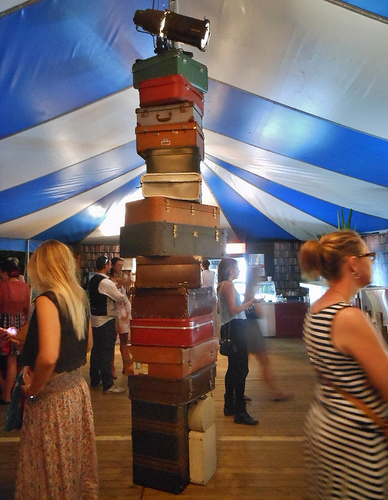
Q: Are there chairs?
A: No, there are no chairs.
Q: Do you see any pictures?
A: No, there are no pictures.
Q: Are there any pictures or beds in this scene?
A: No, there are no pictures or beds.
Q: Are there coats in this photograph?
A: Yes, there is a coat.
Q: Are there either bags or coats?
A: Yes, there is a coat.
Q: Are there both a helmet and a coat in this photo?
A: No, there is a coat but no helmets.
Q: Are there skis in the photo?
A: No, there are no skis.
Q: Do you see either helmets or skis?
A: No, there are no skis or helmets.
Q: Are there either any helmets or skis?
A: No, there are no skis or helmets.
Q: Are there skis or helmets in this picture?
A: No, there are no skis or helmets.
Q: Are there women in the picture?
A: Yes, there is a woman.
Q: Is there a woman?
A: Yes, there is a woman.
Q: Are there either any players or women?
A: Yes, there is a woman.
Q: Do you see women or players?
A: Yes, there is a woman.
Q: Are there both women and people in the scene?
A: Yes, there are both a woman and people.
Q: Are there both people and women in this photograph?
A: Yes, there are both a woman and people.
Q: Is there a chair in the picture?
A: No, there are no chairs.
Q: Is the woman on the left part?
A: Yes, the woman is on the left of the image.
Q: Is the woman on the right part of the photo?
A: No, the woman is on the left of the image.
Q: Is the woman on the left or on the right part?
A: The woman is on the left of the image.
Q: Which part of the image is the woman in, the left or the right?
A: The woman is on the left of the image.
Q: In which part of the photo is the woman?
A: The woman is on the left of the image.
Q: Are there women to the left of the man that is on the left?
A: Yes, there is a woman to the left of the man.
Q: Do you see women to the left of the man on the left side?
A: Yes, there is a woman to the left of the man.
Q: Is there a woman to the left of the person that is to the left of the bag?
A: Yes, there is a woman to the left of the man.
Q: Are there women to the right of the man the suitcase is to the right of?
A: No, the woman is to the left of the man.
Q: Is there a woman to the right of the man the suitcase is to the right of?
A: No, the woman is to the left of the man.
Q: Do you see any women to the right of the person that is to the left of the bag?
A: No, the woman is to the left of the man.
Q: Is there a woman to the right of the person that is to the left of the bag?
A: No, the woman is to the left of the man.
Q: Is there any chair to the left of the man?
A: No, there is a woman to the left of the man.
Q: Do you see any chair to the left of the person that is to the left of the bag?
A: No, there is a woman to the left of the man.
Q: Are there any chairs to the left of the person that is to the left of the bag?
A: No, there is a woman to the left of the man.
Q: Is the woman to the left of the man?
A: Yes, the woman is to the left of the man.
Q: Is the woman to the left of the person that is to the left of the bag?
A: Yes, the woman is to the left of the man.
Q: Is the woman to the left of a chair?
A: No, the woman is to the left of the man.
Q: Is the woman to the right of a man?
A: No, the woman is to the left of a man.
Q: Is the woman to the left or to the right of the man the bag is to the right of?
A: The woman is to the left of the man.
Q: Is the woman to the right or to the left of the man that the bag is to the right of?
A: The woman is to the left of the man.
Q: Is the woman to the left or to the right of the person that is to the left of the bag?
A: The woman is to the left of the man.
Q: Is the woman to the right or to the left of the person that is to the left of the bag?
A: The woman is to the left of the man.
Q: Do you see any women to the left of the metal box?
A: Yes, there is a woman to the left of the box.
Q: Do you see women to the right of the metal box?
A: No, the woman is to the left of the box.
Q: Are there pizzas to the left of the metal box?
A: No, there is a woman to the left of the box.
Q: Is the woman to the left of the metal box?
A: Yes, the woman is to the left of the box.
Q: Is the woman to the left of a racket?
A: No, the woman is to the left of the box.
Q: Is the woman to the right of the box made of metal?
A: No, the woman is to the left of the box.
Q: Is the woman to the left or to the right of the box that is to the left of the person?
A: The woman is to the left of the box.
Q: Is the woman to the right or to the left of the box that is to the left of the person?
A: The woman is to the left of the box.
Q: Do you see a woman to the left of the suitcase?
A: Yes, there is a woman to the left of the suitcase.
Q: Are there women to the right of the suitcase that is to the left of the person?
A: No, the woman is to the left of the suitcase.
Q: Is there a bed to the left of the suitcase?
A: No, there is a woman to the left of the suitcase.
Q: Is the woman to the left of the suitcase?
A: Yes, the woman is to the left of the suitcase.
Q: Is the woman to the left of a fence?
A: No, the woman is to the left of the suitcase.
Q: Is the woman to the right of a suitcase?
A: No, the woman is to the left of a suitcase.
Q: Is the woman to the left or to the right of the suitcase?
A: The woman is to the left of the suitcase.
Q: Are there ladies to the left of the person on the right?
A: Yes, there is a lady to the left of the person.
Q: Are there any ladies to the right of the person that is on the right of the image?
A: No, the lady is to the left of the person.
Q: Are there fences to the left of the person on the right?
A: No, there is a lady to the left of the person.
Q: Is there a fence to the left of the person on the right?
A: No, there is a lady to the left of the person.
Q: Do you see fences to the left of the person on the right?
A: No, there is a lady to the left of the person.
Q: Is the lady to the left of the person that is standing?
A: Yes, the lady is to the left of the person.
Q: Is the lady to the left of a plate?
A: No, the lady is to the left of the person.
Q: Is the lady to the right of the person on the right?
A: No, the lady is to the left of the person.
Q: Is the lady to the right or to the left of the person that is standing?
A: The lady is to the left of the person.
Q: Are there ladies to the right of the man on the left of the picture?
A: Yes, there is a lady to the right of the man.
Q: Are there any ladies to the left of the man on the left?
A: No, the lady is to the right of the man.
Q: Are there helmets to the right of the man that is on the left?
A: No, there is a lady to the right of the man.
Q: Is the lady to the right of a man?
A: Yes, the lady is to the right of a man.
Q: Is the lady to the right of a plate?
A: No, the lady is to the right of a man.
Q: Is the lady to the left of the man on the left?
A: No, the lady is to the right of the man.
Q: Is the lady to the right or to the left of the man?
A: The lady is to the right of the man.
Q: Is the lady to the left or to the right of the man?
A: The lady is to the right of the man.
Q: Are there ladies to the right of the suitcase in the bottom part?
A: Yes, there is a lady to the right of the suitcase.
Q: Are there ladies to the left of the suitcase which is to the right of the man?
A: No, the lady is to the right of the suitcase.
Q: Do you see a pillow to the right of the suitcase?
A: No, there is a lady to the right of the suitcase.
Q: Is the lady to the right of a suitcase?
A: Yes, the lady is to the right of a suitcase.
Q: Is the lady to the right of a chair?
A: No, the lady is to the right of a suitcase.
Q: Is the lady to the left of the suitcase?
A: No, the lady is to the right of the suitcase.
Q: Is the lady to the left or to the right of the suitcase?
A: The lady is to the right of the suitcase.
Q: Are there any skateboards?
A: No, there are no skateboards.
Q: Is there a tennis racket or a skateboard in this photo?
A: No, there are no skateboards or rackets.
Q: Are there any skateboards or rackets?
A: No, there are no skateboards or rackets.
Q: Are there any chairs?
A: No, there are no chairs.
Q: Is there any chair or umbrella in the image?
A: No, there are no chairs or umbrellas.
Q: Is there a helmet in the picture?
A: No, there are no helmets.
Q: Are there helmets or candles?
A: No, there are no helmets or candles.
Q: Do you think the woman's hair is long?
A: Yes, the hair is long.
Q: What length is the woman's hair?
A: The hair is long.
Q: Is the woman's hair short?
A: No, the hair is long.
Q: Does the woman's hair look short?
A: No, the hair is long.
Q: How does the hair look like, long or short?
A: The hair is long.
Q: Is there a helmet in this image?
A: No, there are no helmets.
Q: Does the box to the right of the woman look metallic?
A: Yes, the box is metallic.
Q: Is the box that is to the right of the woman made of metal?
A: Yes, the box is made of metal.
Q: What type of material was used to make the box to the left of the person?
A: The box is made of metal.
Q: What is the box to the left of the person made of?
A: The box is made of metal.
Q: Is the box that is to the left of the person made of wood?
A: No, the box is made of metal.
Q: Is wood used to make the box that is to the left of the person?
A: No, the box is made of metal.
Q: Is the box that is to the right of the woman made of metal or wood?
A: The box is made of metal.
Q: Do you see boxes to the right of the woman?
A: Yes, there is a box to the right of the woman.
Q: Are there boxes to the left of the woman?
A: No, the box is to the right of the woman.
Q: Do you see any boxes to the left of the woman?
A: No, the box is to the right of the woman.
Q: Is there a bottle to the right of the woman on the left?
A: No, there is a box to the right of the woman.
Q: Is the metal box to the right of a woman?
A: Yes, the box is to the right of a woman.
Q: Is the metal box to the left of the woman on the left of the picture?
A: No, the box is to the right of the woman.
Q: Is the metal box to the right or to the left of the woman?
A: The box is to the right of the woman.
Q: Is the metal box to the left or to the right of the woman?
A: The box is to the right of the woman.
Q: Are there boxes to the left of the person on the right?
A: Yes, there is a box to the left of the person.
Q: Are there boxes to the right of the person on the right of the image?
A: No, the box is to the left of the person.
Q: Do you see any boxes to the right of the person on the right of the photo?
A: No, the box is to the left of the person.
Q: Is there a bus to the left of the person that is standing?
A: No, there is a box to the left of the person.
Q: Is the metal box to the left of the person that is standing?
A: Yes, the box is to the left of the person.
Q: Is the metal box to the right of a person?
A: No, the box is to the left of a person.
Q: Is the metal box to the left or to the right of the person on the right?
A: The box is to the left of the person.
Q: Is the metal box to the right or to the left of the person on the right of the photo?
A: The box is to the left of the person.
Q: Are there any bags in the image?
A: Yes, there is a bag.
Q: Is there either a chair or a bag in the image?
A: Yes, there is a bag.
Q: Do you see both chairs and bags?
A: No, there is a bag but no chairs.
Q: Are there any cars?
A: No, there are no cars.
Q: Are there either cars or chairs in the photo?
A: No, there are no cars or chairs.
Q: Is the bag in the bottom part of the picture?
A: Yes, the bag is in the bottom of the image.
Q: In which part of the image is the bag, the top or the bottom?
A: The bag is in the bottom of the image.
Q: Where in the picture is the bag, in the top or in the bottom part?
A: The bag is in the bottom of the image.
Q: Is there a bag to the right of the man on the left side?
A: Yes, there is a bag to the right of the man.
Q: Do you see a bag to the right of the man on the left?
A: Yes, there is a bag to the right of the man.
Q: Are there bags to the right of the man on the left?
A: Yes, there is a bag to the right of the man.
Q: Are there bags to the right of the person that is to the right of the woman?
A: Yes, there is a bag to the right of the man.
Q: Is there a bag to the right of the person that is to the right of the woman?
A: Yes, there is a bag to the right of the man.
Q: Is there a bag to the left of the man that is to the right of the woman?
A: No, the bag is to the right of the man.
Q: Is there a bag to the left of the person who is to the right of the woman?
A: No, the bag is to the right of the man.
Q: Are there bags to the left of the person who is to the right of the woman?
A: No, the bag is to the right of the man.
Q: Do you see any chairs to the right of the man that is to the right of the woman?
A: No, there is a bag to the right of the man.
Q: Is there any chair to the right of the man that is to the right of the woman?
A: No, there is a bag to the right of the man.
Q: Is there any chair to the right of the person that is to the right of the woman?
A: No, there is a bag to the right of the man.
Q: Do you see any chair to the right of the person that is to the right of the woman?
A: No, there is a bag to the right of the man.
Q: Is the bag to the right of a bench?
A: No, the bag is to the right of the man.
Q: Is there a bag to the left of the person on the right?
A: Yes, there is a bag to the left of the person.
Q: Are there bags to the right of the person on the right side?
A: No, the bag is to the left of the person.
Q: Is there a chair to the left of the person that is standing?
A: No, there is a bag to the left of the person.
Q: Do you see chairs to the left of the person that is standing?
A: No, there is a bag to the left of the person.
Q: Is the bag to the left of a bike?
A: No, the bag is to the left of the person.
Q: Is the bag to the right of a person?
A: No, the bag is to the left of a person.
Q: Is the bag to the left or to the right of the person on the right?
A: The bag is to the left of the person.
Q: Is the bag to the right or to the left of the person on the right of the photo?
A: The bag is to the left of the person.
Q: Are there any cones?
A: No, there are no cones.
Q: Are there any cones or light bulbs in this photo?
A: No, there are no cones or light bulbs.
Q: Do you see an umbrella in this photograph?
A: No, there are no umbrellas.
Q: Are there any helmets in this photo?
A: No, there are no helmets.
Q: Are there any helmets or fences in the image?
A: No, there are no helmets or fences.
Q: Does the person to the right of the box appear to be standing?
A: Yes, the person is standing.